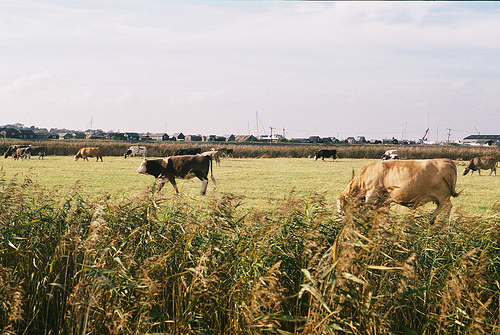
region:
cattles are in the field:
[48, 127, 466, 292]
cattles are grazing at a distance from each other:
[78, 139, 462, 255]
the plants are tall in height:
[128, 209, 338, 311]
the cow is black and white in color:
[144, 154, 225, 196]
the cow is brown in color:
[360, 157, 487, 217]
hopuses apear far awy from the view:
[106, 129, 233, 148]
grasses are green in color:
[261, 159, 297, 189]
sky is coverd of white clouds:
[266, 67, 299, 102]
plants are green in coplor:
[95, 209, 265, 292]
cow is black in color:
[318, 141, 340, 156]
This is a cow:
[125, 150, 227, 216]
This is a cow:
[326, 154, 473, 251]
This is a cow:
[368, 130, 411, 198]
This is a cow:
[308, 142, 343, 167]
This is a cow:
[169, 140, 204, 165]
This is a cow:
[118, 133, 157, 160]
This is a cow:
[70, 139, 107, 167]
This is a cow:
[11, 144, 33, 164]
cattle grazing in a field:
[0, 84, 497, 267]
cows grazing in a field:
[5, 100, 497, 263]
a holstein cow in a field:
[127, 135, 242, 216]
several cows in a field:
[1, 114, 242, 233]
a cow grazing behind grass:
[324, 153, 465, 333]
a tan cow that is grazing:
[327, 155, 463, 332]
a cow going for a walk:
[128, 148, 235, 218]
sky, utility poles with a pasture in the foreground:
[232, 91, 299, 302]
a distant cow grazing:
[458, 127, 498, 186]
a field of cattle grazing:
[0, 110, 497, 235]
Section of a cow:
[330, 155, 462, 245]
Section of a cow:
[135, 152, 220, 208]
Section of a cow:
[308, 144, 346, 166]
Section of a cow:
[460, 150, 497, 183]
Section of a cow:
[377, 143, 397, 155]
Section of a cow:
[121, 140, 146, 161]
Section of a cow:
[70, 143, 105, 165]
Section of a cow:
[8, 143, 35, 163]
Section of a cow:
[24, 137, 53, 165]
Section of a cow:
[2, 137, 26, 160]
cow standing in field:
[329, 148, 459, 221]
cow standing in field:
[464, 149, 497, 179]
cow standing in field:
[382, 148, 397, 158]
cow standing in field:
[313, 144, 339, 161]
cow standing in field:
[139, 150, 213, 192]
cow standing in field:
[194, 146, 220, 164]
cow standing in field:
[121, 144, 146, 159]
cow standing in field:
[171, 145, 201, 156]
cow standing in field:
[23, 143, 48, 161]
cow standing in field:
[72, 140, 104, 167]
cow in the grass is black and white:
[130, 149, 226, 214]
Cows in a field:
[14, 138, 492, 217]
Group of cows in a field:
[8, 140, 495, 219]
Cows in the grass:
[6, 137, 491, 220]